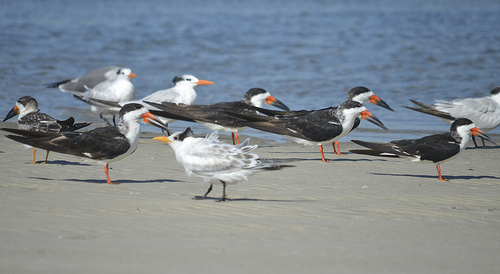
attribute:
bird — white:
[155, 129, 289, 203]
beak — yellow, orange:
[156, 137, 171, 142]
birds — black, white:
[143, 86, 380, 162]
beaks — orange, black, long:
[270, 94, 290, 113]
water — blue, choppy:
[7, 1, 499, 111]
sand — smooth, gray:
[9, 181, 498, 267]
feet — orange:
[319, 141, 345, 162]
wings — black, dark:
[146, 97, 252, 139]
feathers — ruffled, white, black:
[186, 138, 260, 184]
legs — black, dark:
[203, 179, 231, 204]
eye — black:
[174, 136, 181, 139]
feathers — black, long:
[163, 83, 267, 128]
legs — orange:
[315, 140, 341, 168]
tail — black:
[148, 104, 206, 122]